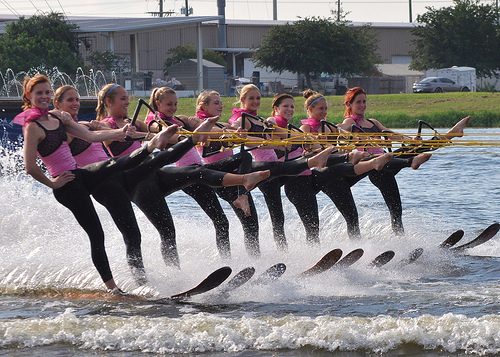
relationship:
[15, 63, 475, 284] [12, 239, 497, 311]
performers on waterskis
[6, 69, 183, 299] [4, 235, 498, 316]
girl on waterskis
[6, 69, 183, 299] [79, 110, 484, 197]
girl lift foot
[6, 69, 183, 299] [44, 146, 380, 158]
girl wears pink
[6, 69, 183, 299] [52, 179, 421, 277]
girl wears black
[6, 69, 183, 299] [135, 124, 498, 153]
girl holds rope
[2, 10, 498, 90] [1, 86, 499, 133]
building on shore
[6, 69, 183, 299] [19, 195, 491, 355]
girl in water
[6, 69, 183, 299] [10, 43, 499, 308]
girl doing tricks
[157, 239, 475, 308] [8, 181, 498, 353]
waterskis in water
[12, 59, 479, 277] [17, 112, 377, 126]
girls wear scarves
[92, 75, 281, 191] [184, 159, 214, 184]
girl has knee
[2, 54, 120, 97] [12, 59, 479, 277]
fountain behind girls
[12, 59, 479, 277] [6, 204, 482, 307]
girls make big splash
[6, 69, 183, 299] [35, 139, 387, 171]
girl dress pink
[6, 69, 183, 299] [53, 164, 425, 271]
girl dress black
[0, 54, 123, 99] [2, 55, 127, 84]
fountain sprays water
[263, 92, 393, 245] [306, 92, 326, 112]
woman with headband